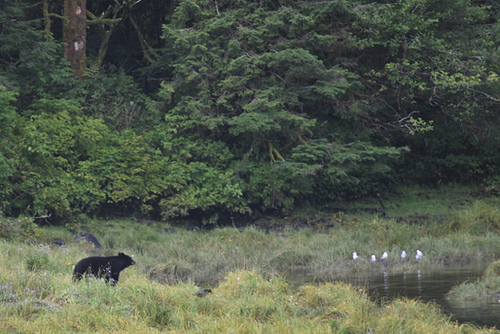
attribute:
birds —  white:
[330, 230, 463, 286]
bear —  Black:
[72, 250, 137, 287]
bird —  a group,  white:
[349, 250, 361, 260]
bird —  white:
[369, 253, 377, 261]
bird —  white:
[380, 251, 389, 261]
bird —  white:
[399, 250, 407, 260]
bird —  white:
[413, 248, 424, 259]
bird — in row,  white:
[414, 245, 425, 263]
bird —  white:
[395, 249, 407, 258]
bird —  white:
[381, 248, 391, 263]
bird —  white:
[369, 252, 377, 264]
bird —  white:
[349, 249, 363, 262]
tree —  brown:
[32, 14, 289, 236]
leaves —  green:
[363, 58, 427, 108]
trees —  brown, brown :
[3, 5, 498, 231]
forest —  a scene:
[3, 5, 498, 222]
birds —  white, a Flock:
[299, 208, 450, 287]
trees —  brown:
[217, 14, 344, 179]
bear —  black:
[70, 247, 135, 284]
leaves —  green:
[15, 117, 162, 205]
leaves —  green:
[1, 2, 499, 214]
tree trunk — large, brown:
[58, 0, 96, 96]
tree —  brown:
[61, 0, 88, 74]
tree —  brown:
[38, 0, 55, 40]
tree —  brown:
[325, 27, 467, 165]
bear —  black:
[71, 252, 135, 283]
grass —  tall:
[0, 184, 499, 330]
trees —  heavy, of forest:
[138, 15, 383, 208]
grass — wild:
[68, 181, 489, 287]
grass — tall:
[17, 163, 478, 309]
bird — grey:
[28, 250, 270, 291]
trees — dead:
[85, 4, 175, 80]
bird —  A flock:
[347, 250, 364, 265]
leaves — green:
[170, 89, 254, 139]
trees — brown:
[35, 15, 144, 138]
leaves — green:
[161, 52, 351, 188]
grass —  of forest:
[332, 158, 494, 233]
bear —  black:
[70, 250, 135, 289]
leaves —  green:
[406, 111, 435, 138]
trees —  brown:
[60, 0, 90, 78]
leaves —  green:
[406, 115, 435, 136]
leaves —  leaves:
[407, 112, 435, 137]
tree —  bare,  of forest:
[60, 0, 87, 80]